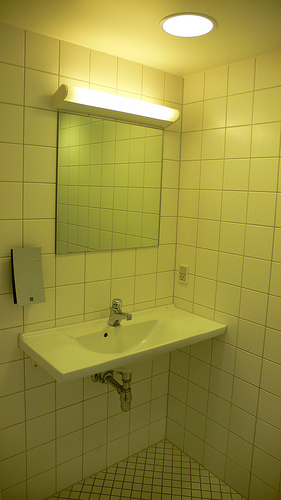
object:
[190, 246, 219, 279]
tile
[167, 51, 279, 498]
wall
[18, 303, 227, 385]
sink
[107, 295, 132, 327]
faucet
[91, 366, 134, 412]
pipes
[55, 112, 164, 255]
mirror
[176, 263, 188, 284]
outlet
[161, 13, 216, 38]
light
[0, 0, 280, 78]
ceiling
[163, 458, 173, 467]
tile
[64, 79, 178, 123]
beam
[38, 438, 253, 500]
tiles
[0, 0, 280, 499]
restroom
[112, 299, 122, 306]
tap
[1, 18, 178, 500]
walls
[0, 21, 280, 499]
tiles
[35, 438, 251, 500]
floor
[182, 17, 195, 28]
light bulb